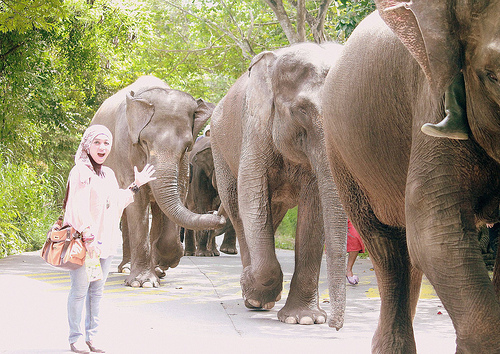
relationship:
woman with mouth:
[41, 119, 145, 353] [95, 149, 110, 161]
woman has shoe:
[41, 119, 145, 353] [85, 329, 106, 352]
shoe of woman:
[85, 329, 106, 352] [41, 119, 145, 353]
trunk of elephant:
[299, 156, 367, 340] [204, 14, 347, 340]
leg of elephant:
[205, 169, 287, 306] [204, 14, 347, 340]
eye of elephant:
[301, 97, 308, 118] [204, 14, 347, 340]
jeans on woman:
[66, 263, 106, 333] [41, 119, 145, 353]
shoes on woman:
[71, 317, 106, 354] [41, 119, 145, 353]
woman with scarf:
[41, 119, 145, 353] [71, 122, 115, 157]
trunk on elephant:
[299, 156, 367, 340] [204, 14, 347, 340]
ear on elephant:
[242, 48, 280, 148] [204, 14, 347, 340]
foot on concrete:
[236, 238, 299, 335] [153, 201, 260, 322]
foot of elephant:
[236, 238, 299, 335] [204, 14, 347, 340]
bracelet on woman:
[123, 175, 146, 203] [41, 119, 145, 353]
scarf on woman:
[71, 122, 115, 157] [41, 119, 145, 353]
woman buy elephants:
[41, 119, 145, 353] [56, 42, 479, 330]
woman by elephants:
[41, 119, 145, 353] [56, 42, 479, 330]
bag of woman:
[39, 219, 92, 270] [41, 119, 145, 353]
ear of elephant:
[242, 48, 280, 148] [204, 14, 347, 340]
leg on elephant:
[205, 169, 287, 306] [204, 14, 347, 340]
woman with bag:
[41, 119, 145, 353] [39, 219, 92, 270]